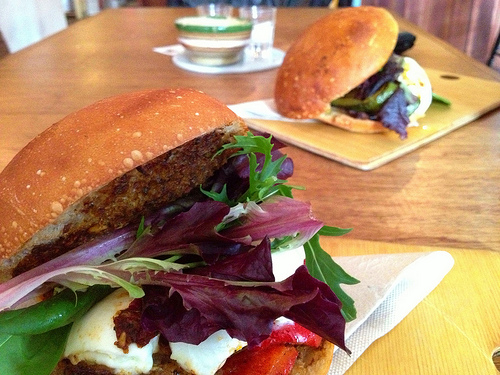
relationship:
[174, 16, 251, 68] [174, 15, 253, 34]
bowl has trim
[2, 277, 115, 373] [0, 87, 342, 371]
lettuce on hamburger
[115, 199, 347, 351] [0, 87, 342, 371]
lettuce on hamburger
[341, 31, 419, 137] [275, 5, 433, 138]
lettuce on hamburger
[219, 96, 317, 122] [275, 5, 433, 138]
napkin underneath hamburger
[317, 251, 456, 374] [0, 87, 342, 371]
napkin underneath hamburger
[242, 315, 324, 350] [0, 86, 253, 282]
tomato underneath bun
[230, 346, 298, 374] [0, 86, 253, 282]
tomato underneath bun